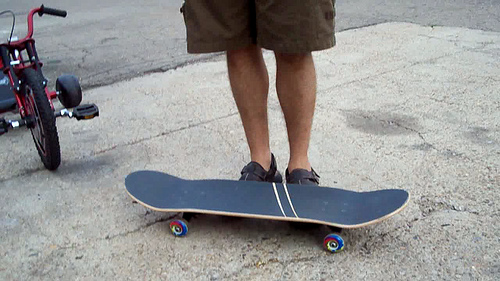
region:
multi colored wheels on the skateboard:
[163, 217, 346, 257]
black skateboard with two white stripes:
[128, 169, 401, 225]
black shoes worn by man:
[238, 147, 328, 185]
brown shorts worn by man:
[179, 2, 339, 57]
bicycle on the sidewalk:
[2, 3, 113, 177]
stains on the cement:
[343, 99, 483, 159]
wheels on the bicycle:
[5, 71, 76, 170]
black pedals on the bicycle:
[2, 98, 99, 144]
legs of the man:
[223, 57, 318, 159]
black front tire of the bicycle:
[22, 73, 62, 161]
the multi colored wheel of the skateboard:
[170, 216, 185, 236]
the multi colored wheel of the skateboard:
[322, 233, 343, 251]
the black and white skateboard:
[125, 168, 407, 230]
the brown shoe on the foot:
[237, 153, 279, 183]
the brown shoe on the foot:
[283, 163, 324, 188]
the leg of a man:
[227, 45, 275, 172]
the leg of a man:
[274, 45, 321, 168]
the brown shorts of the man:
[181, 2, 338, 56]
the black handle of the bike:
[35, 2, 67, 21]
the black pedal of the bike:
[72, 101, 103, 119]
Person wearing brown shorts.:
[236, 13, 314, 33]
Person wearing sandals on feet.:
[243, 158, 338, 183]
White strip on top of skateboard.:
[261, 185, 312, 216]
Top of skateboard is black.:
[154, 170, 341, 211]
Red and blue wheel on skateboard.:
[321, 229, 356, 261]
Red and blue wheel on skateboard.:
[160, 213, 212, 248]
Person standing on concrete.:
[229, 131, 350, 213]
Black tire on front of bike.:
[26, 83, 75, 156]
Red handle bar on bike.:
[10, 10, 53, 56]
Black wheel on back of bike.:
[53, 70, 95, 112]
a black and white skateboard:
[112, 154, 462, 266]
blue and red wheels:
[169, 218, 363, 275]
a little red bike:
[5, 9, 109, 195]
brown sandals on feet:
[226, 129, 360, 230]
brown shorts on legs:
[176, 2, 355, 212]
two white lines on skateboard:
[261, 174, 321, 244]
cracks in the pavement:
[168, 102, 482, 274]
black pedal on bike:
[67, 94, 108, 140]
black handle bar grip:
[37, 1, 68, 26]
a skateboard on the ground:
[100, 158, 460, 268]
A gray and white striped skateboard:
[111, 148, 451, 258]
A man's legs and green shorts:
[151, 2, 391, 193]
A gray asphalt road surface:
[78, 5, 155, 69]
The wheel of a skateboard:
[310, 228, 357, 258]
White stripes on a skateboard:
[257, 170, 329, 225]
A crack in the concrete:
[97, 217, 159, 243]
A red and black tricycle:
[5, 1, 105, 182]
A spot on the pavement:
[336, 98, 440, 139]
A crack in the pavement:
[96, 217, 158, 249]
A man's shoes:
[233, 145, 323, 203]